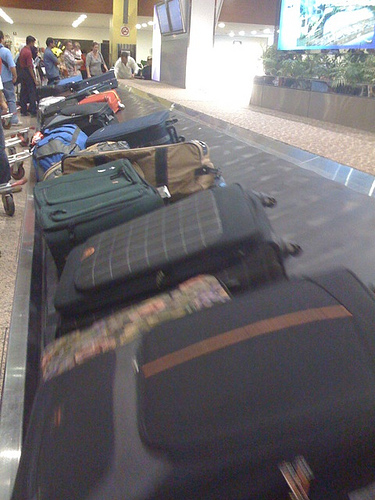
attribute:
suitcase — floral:
[41, 276, 233, 370]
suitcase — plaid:
[50, 185, 283, 304]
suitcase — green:
[40, 160, 149, 241]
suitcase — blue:
[85, 117, 178, 144]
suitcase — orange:
[81, 87, 128, 110]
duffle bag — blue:
[28, 124, 92, 155]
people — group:
[0, 34, 136, 71]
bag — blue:
[33, 113, 76, 172]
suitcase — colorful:
[31, 270, 232, 369]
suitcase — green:
[33, 156, 155, 240]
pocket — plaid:
[70, 186, 226, 295]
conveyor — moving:
[28, 64, 368, 494]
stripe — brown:
[139, 301, 353, 380]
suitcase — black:
[6, 264, 370, 494]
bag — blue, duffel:
[30, 121, 87, 179]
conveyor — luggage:
[248, 67, 373, 136]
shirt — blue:
[42, 47, 60, 82]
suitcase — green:
[24, 154, 169, 273]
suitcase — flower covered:
[36, 270, 229, 381]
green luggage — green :
[26, 165, 154, 228]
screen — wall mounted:
[151, 4, 180, 38]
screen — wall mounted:
[167, 2, 188, 31]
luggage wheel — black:
[251, 186, 278, 211]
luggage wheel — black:
[282, 234, 313, 264]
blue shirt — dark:
[41, 39, 64, 84]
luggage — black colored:
[85, 113, 208, 162]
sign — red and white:
[120, 26, 134, 38]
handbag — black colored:
[99, 58, 111, 71]